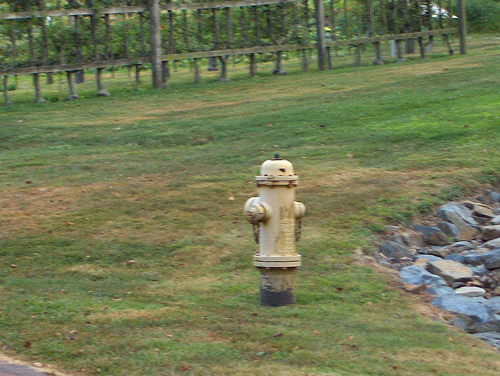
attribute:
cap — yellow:
[242, 200, 272, 225]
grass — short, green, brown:
[0, 32, 498, 374]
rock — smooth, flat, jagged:
[418, 249, 476, 281]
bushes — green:
[29, 22, 258, 131]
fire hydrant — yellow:
[237, 147, 312, 310]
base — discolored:
[243, 261, 304, 308]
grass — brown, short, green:
[78, 108, 443, 176]